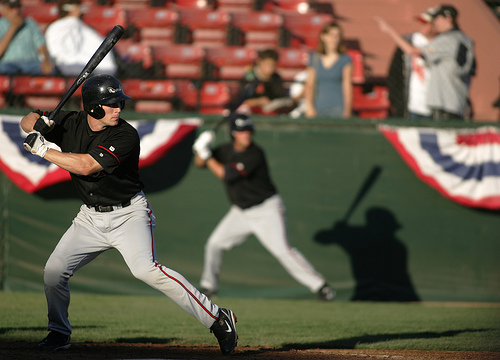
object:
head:
[80, 77, 129, 127]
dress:
[305, 51, 352, 117]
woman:
[301, 22, 352, 118]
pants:
[40, 193, 224, 339]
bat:
[21, 23, 124, 151]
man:
[19, 68, 237, 358]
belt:
[69, 188, 150, 213]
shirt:
[19, 113, 140, 207]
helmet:
[79, 72, 128, 122]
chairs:
[346, 78, 394, 117]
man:
[195, 115, 336, 300]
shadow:
[305, 162, 420, 304]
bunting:
[374, 116, 500, 212]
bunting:
[1, 109, 203, 198]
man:
[372, 6, 480, 122]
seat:
[160, 40, 206, 75]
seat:
[231, 5, 306, 54]